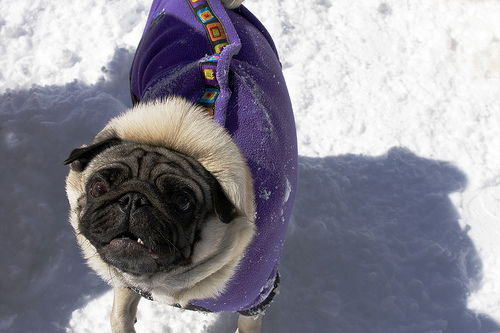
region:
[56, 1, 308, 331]
The pug dog is biege and black.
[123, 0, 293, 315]
The pug dog is wearing a purple vest.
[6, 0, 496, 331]
The pug dog is standing in snow.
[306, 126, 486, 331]
A shadow of the dog.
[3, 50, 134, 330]
A shadow on the snow.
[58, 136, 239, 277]
The dog's face is mostly black.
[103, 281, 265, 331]
The dog has two front legs.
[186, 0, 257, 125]
The closure on the purple dog vest.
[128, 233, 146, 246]
The dog's teeth are partially visible.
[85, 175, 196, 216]
The dog has two brown eyes.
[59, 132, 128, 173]
Right ear of pug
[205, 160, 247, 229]
Left ear of pug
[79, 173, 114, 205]
Right eye of pug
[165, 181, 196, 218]
Left eye of pug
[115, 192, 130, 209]
Right nostril of pug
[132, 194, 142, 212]
Left nostril of pug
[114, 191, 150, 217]
Nose of gray pug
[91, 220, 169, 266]
Mouth of gray pug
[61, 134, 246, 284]
Head of gray pug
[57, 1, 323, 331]
Pug wearing purple and white jacket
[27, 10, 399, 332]
A pug in the snow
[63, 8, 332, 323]
A jacket on a dog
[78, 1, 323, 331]
A purple jacket on a dog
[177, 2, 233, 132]
A mulit-colored stripe on a dog jacket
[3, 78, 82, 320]
A shadow in the snow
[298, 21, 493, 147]
Snow on the ground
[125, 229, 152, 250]
Teeth in a dog's mouth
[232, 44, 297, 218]
Purple fleece on a dog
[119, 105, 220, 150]
Dog fur on a pug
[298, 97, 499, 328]
The shadow of a dog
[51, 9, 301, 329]
a dog looking up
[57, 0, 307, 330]
the dog is a pug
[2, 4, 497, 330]
the dog is standing in the snow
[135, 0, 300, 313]
the dog is wearing a blanket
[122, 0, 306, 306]
the blanket is purple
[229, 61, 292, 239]
there is snow on the blanket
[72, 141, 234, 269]
the dog's face is black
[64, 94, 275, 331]
the dog's fur is white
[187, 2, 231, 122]
a colored strip on the blanket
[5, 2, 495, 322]
the snow is well trampled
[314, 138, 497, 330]
a shadow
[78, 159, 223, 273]
a pug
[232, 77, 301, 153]
a purple blanket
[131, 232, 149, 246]
the dogs teeth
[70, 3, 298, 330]
the dog is standing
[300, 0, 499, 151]
the snow is white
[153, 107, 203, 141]
the dogs fur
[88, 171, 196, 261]
the dog has a black face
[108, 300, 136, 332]
the dogs leg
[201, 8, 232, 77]
designs on the blanket